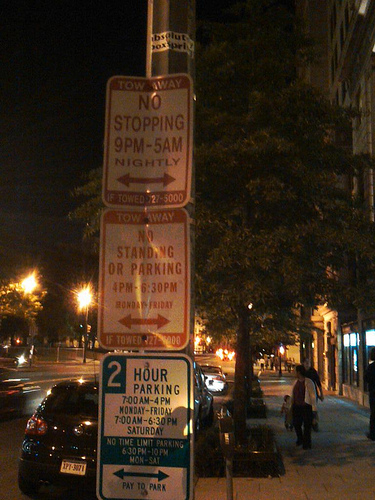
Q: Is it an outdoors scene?
A: Yes, it is outdoors.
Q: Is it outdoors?
A: Yes, it is outdoors.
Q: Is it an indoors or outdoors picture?
A: It is outdoors.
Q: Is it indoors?
A: No, it is outdoors.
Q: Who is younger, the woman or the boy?
A: The boy is younger than the woman.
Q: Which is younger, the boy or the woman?
A: The boy is younger than the woman.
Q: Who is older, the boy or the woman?
A: The woman is older than the boy.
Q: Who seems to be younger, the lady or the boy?
A: The boy is younger than the lady.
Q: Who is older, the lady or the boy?
A: The lady is older than the boy.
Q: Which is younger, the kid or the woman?
A: The kid is younger than the woman.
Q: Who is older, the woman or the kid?
A: The woman is older than the kid.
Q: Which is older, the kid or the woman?
A: The woman is older than the kid.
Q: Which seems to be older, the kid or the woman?
A: The woman is older than the kid.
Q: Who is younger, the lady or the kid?
A: The kid is younger than the lady.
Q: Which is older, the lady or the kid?
A: The lady is older than the kid.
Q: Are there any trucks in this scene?
A: No, there are no trucks.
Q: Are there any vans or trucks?
A: No, there are no trucks or vans.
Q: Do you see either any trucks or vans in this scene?
A: No, there are no trucks or vans.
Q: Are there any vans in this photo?
A: No, there are no vans.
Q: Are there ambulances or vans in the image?
A: No, there are no vans or ambulances.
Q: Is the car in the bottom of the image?
A: Yes, the car is in the bottom of the image.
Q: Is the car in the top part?
A: No, the car is in the bottom of the image.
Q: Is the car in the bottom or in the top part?
A: The car is in the bottom of the image.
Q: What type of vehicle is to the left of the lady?
A: The vehicle is a car.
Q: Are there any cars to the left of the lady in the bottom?
A: Yes, there is a car to the left of the lady.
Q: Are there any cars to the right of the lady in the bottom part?
A: No, the car is to the left of the lady.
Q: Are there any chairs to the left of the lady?
A: No, there is a car to the left of the lady.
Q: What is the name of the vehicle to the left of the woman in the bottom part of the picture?
A: The vehicle is a car.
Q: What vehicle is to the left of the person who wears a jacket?
A: The vehicle is a car.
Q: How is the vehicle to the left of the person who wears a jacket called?
A: The vehicle is a car.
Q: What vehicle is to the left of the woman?
A: The vehicle is a car.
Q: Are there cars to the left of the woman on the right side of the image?
A: Yes, there is a car to the left of the woman.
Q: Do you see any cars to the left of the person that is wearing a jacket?
A: Yes, there is a car to the left of the woman.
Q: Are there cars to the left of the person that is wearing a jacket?
A: Yes, there is a car to the left of the woman.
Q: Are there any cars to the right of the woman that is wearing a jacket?
A: No, the car is to the left of the woman.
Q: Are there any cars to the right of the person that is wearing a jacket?
A: No, the car is to the left of the woman.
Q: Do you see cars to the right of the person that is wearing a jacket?
A: No, the car is to the left of the woman.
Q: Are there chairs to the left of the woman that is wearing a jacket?
A: No, there is a car to the left of the woman.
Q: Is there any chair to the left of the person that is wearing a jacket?
A: No, there is a car to the left of the woman.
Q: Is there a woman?
A: Yes, there is a woman.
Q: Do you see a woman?
A: Yes, there is a woman.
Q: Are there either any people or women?
A: Yes, there is a woman.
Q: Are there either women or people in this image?
A: Yes, there is a woman.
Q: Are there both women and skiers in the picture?
A: No, there is a woman but no skiers.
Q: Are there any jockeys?
A: No, there are no jockeys.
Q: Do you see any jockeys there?
A: No, there are no jockeys.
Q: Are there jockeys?
A: No, there are no jockeys.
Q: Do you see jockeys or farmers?
A: No, there are no jockeys or farmers.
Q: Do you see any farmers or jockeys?
A: No, there are no jockeys or farmers.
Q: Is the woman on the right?
A: Yes, the woman is on the right of the image.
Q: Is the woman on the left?
A: No, the woman is on the right of the image.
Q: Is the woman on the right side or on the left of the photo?
A: The woman is on the right of the image.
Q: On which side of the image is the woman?
A: The woman is on the right of the image.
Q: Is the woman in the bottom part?
A: Yes, the woman is in the bottom of the image.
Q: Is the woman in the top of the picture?
A: No, the woman is in the bottom of the image.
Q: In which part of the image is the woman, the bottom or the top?
A: The woman is in the bottom of the image.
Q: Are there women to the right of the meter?
A: Yes, there is a woman to the right of the meter.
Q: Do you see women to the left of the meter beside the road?
A: No, the woman is to the right of the meter.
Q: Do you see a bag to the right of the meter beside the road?
A: No, there is a woman to the right of the meter.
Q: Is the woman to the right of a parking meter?
A: Yes, the woman is to the right of a parking meter.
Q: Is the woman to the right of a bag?
A: No, the woman is to the right of a parking meter.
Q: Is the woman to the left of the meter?
A: No, the woman is to the right of the meter.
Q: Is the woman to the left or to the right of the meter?
A: The woman is to the right of the meter.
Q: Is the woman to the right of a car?
A: Yes, the woman is to the right of a car.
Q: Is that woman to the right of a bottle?
A: No, the woman is to the right of a car.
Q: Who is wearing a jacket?
A: The woman is wearing a jacket.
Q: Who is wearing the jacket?
A: The woman is wearing a jacket.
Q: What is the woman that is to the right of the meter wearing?
A: The woman is wearing a jacket.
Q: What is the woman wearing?
A: The woman is wearing a jacket.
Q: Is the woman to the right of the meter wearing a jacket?
A: Yes, the woman is wearing a jacket.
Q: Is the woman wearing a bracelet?
A: No, the woman is wearing a jacket.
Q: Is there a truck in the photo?
A: No, there are no trucks.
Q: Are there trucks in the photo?
A: No, there are no trucks.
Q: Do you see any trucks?
A: No, there are no trucks.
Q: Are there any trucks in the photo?
A: No, there are no trucks.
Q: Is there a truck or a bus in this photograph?
A: No, there are no trucks or buses.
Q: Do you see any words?
A: Yes, there are words.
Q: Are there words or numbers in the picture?
A: Yes, there are words.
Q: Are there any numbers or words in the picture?
A: Yes, there are words.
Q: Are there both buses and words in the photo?
A: No, there are words but no buses.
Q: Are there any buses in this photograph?
A: No, there are no buses.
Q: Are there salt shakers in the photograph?
A: No, there are no salt shakers.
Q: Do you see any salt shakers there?
A: No, there are no salt shakers.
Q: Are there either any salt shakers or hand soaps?
A: No, there are no salt shakers or hand soaps.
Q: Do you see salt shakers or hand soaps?
A: No, there are no salt shakers or hand soaps.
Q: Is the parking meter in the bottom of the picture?
A: Yes, the parking meter is in the bottom of the image.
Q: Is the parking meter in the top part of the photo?
A: No, the parking meter is in the bottom of the image.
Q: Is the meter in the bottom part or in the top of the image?
A: The meter is in the bottom of the image.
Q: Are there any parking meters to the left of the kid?
A: Yes, there is a parking meter to the left of the kid.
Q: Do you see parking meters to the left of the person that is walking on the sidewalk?
A: Yes, there is a parking meter to the left of the kid.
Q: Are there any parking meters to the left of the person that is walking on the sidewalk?
A: Yes, there is a parking meter to the left of the kid.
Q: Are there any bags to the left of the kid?
A: No, there is a parking meter to the left of the kid.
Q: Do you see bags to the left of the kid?
A: No, there is a parking meter to the left of the kid.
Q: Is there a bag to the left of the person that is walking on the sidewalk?
A: No, there is a parking meter to the left of the kid.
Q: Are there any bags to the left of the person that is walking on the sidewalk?
A: No, there is a parking meter to the left of the kid.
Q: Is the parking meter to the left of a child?
A: Yes, the parking meter is to the left of a child.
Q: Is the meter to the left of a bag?
A: No, the meter is to the left of a child.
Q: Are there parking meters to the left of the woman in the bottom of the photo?
A: Yes, there is a parking meter to the left of the woman.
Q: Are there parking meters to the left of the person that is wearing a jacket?
A: Yes, there is a parking meter to the left of the woman.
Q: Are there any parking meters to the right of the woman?
A: No, the parking meter is to the left of the woman.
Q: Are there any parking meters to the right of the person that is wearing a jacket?
A: No, the parking meter is to the left of the woman.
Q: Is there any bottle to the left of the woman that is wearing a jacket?
A: No, there is a parking meter to the left of the woman.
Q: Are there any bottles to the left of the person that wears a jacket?
A: No, there is a parking meter to the left of the woman.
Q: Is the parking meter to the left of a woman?
A: Yes, the parking meter is to the left of a woman.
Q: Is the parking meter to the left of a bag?
A: No, the parking meter is to the left of a woman.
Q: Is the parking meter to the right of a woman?
A: No, the parking meter is to the left of a woman.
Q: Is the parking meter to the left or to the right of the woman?
A: The parking meter is to the left of the woman.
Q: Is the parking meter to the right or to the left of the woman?
A: The parking meter is to the left of the woman.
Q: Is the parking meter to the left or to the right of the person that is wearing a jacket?
A: The parking meter is to the left of the woman.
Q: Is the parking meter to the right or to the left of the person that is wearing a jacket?
A: The parking meter is to the left of the woman.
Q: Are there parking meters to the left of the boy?
A: Yes, there is a parking meter to the left of the boy.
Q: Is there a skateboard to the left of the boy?
A: No, there is a parking meter to the left of the boy.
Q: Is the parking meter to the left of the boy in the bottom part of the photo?
A: Yes, the parking meter is to the left of the boy.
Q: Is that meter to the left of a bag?
A: No, the meter is to the left of the boy.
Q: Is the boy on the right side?
A: Yes, the boy is on the right of the image.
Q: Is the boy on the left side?
A: No, the boy is on the right of the image.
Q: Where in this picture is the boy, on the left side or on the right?
A: The boy is on the right of the image.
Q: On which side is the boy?
A: The boy is on the right of the image.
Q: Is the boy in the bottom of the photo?
A: Yes, the boy is in the bottom of the image.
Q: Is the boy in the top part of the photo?
A: No, the boy is in the bottom of the image.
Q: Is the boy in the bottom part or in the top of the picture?
A: The boy is in the bottom of the image.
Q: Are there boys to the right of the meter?
A: Yes, there is a boy to the right of the meter.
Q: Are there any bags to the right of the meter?
A: No, there is a boy to the right of the meter.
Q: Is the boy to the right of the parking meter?
A: Yes, the boy is to the right of the parking meter.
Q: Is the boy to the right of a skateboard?
A: No, the boy is to the right of the parking meter.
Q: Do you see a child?
A: Yes, there is a child.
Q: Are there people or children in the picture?
A: Yes, there is a child.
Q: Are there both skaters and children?
A: No, there is a child but no skaters.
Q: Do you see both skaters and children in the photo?
A: No, there is a child but no skaters.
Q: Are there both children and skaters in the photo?
A: No, there is a child but no skaters.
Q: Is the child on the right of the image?
A: Yes, the child is on the right of the image.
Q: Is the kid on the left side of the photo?
A: No, the kid is on the right of the image.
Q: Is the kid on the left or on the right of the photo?
A: The kid is on the right of the image.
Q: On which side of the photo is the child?
A: The child is on the right of the image.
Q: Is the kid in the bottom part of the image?
A: Yes, the kid is in the bottom of the image.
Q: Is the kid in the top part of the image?
A: No, the kid is in the bottom of the image.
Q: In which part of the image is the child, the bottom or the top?
A: The child is in the bottom of the image.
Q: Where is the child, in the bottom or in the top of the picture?
A: The child is in the bottom of the image.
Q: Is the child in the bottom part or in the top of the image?
A: The child is in the bottom of the image.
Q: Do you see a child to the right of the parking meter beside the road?
A: Yes, there is a child to the right of the meter.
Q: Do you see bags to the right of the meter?
A: No, there is a child to the right of the meter.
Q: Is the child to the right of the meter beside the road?
A: Yes, the child is to the right of the parking meter.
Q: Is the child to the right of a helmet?
A: No, the child is to the right of the parking meter.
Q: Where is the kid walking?
A: The kid is walking on the sidewalk.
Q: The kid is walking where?
A: The kid is walking on the sidewalk.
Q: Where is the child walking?
A: The kid is walking on the sidewalk.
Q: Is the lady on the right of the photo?
A: Yes, the lady is on the right of the image.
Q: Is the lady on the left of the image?
A: No, the lady is on the right of the image.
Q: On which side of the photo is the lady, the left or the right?
A: The lady is on the right of the image.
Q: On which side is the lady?
A: The lady is on the right of the image.